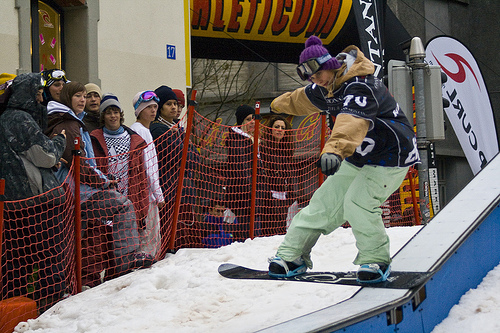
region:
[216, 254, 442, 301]
Snowboard under a man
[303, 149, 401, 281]
Green pants on a snowboarder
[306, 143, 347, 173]
Gray glove on a snowboarder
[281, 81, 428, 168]
Jacket on a snowboarder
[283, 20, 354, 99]
Purple hat on a snowboarder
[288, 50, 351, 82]
Goggles on a snowboarder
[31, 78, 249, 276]
People watching a snowboarder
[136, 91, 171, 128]
Blue goggles on a head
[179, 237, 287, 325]
White snow on the ground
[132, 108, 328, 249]
Orange fence by snow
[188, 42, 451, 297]
Person on a snowboard.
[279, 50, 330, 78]
Goggles on the forehead.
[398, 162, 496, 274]
The top of the ramp is white.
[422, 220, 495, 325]
Side of the ramp is blue.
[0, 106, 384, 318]
Snow fence in front of the people.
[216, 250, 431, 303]
The snowboard is mostly black.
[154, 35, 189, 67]
17 on the building.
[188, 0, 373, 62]
Banner over the building.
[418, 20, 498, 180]
Flag in the background.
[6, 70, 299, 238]
Spectators watching the skateboarder.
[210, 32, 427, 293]
a guy riding his snowboard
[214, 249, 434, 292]
a snowboard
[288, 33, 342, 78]
a purple bonnet with goggles on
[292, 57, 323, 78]
a goggle on the head of the guy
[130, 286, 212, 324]
snow on the ground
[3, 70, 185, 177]
spectators on the side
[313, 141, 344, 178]
a glove the kid is wearing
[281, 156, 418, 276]
a mint green snow pants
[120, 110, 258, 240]
a red fence separating the performer and the spectators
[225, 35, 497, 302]
a snowboarder going down the ramp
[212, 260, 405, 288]
Black snowboard on top of snow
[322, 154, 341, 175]
A glove on the left hand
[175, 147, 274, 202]
A red fence in front of the audience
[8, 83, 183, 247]
People watching the snowboarder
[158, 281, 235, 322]
Snow beneath the snowboard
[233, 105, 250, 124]
Black hat on top of person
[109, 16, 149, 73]
White wall behind audience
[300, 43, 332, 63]
Purple hat on snowboarder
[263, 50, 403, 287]
Snowboarder on a snowboard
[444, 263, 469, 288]
The side of the rail is blue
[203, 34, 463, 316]
person riding on snowboard on ramp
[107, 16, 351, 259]
red fencing between snowboarder and onlookers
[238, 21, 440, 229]
person wearing green pants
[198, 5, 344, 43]
red and yellow sign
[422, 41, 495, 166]
red, white, and black sign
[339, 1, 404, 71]
black and white sign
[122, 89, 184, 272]
person wearing white long-sleeve shirt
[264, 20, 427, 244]
person wearing purple knit hat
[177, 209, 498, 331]
snowboard ramp with blue sides in snow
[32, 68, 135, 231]
person wearing brown and blue jacket